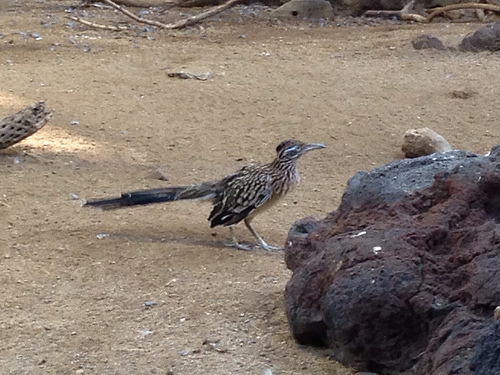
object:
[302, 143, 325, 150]
beak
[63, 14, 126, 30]
branch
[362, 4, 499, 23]
branch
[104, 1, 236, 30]
branch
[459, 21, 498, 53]
rock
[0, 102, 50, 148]
skeleton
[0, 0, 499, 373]
beach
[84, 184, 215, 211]
tail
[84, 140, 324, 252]
bird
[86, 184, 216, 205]
tailfeather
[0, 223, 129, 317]
part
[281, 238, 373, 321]
part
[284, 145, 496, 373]
large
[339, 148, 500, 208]
up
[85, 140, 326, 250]
running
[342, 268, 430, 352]
dark